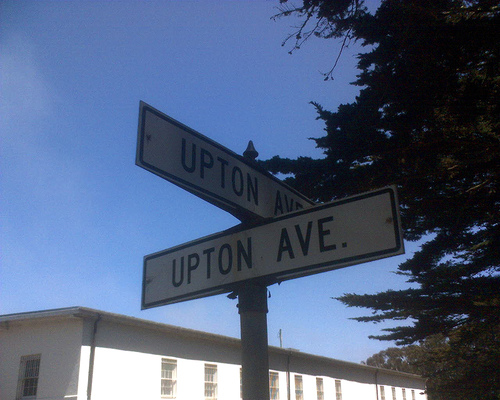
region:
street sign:
[147, 206, 347, 296]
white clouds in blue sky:
[22, 17, 61, 64]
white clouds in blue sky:
[3, 67, 52, 101]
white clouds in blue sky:
[38, 71, 87, 144]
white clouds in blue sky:
[8, 127, 69, 184]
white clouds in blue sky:
[60, 138, 106, 193]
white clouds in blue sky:
[25, 192, 91, 245]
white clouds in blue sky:
[82, 167, 116, 209]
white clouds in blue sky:
[282, 283, 310, 327]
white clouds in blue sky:
[200, 60, 258, 104]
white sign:
[134, 90, 412, 319]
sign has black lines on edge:
[116, 69, 418, 322]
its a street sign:
[108, 91, 426, 321]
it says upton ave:
[113, 208, 384, 313]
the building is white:
[3, 296, 433, 398]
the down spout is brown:
[87, 313, 104, 398]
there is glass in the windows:
[154, 355, 191, 399]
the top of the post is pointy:
[240, 137, 265, 163]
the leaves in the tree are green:
[353, 340, 498, 392]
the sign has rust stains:
[203, 237, 285, 284]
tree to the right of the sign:
[258, 3, 497, 398]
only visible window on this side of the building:
[6, 355, 50, 397]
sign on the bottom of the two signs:
[136, 196, 440, 321]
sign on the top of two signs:
[114, 96, 322, 222]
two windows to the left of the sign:
[135, 349, 232, 397]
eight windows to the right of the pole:
[257, 361, 429, 399]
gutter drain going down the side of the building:
[82, 306, 107, 398]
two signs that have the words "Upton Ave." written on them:
[110, 95, 415, 300]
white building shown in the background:
[0, 298, 436, 398]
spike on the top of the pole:
[232, 133, 272, 163]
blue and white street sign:
[144, 221, 364, 274]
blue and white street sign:
[144, 127, 248, 206]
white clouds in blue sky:
[12, 79, 50, 125]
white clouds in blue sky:
[22, 165, 96, 226]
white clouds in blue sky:
[35, 231, 78, 269]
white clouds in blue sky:
[79, 38, 129, 66]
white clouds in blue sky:
[146, 10, 192, 56]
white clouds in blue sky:
[195, 54, 291, 123]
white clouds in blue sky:
[63, 200, 136, 226]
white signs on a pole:
[119, 93, 413, 398]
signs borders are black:
[117, 90, 414, 317]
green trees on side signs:
[138, 2, 498, 398]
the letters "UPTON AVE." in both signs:
[112, 95, 414, 316]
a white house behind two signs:
[5, 295, 450, 397]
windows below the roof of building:
[136, 357, 426, 398]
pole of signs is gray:
[224, 288, 285, 398]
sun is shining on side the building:
[78, 331, 426, 398]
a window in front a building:
[16, 344, 48, 398]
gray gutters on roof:
[3, 304, 250, 353]